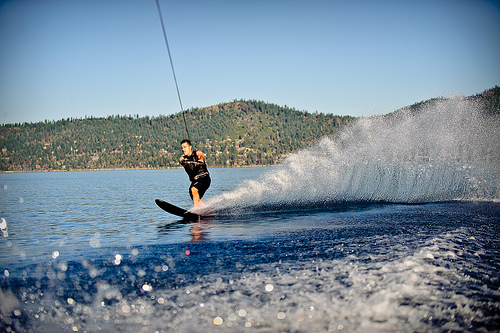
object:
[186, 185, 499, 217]
wave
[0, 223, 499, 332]
wave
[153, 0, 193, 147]
cable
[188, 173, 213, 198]
shorts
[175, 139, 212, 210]
man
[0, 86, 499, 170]
trees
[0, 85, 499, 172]
hills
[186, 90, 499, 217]
splashing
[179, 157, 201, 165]
handle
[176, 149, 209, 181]
life jacket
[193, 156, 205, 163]
hands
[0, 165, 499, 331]
water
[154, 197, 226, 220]
ski